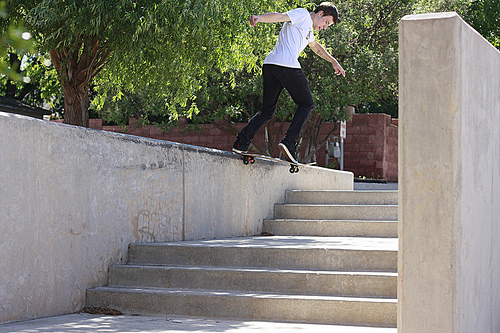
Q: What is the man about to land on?
A: Stairs.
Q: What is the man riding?
A: A skateboard.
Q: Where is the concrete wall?
A: Behind the skateboarder.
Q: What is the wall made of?
A: Concrete.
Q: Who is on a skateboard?
A: A young man.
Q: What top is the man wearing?
A: A white tee shirt.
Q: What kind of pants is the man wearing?
A: Black denim.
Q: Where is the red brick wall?
A: To the skateboarder's left.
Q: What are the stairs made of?
A: Concrete.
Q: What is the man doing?
A: A skateboard trick.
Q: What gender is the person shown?
A: Male.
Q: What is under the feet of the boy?
A: Skateboard.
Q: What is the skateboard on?
A: Edge of a wall.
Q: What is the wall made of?
A: Concrete.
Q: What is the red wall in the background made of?
A: Brick.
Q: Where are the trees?
A: Behind the boy.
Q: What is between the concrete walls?
A: Steps.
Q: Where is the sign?
A: In front of the brick wall.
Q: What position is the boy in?
A: Standing.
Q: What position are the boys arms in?
A: Out to his sides.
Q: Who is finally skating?
A: The man.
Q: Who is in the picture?
A: A boy.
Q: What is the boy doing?
A: Skateboarding.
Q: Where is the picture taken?
A: Some stairs.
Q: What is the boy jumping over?
A: Stairs.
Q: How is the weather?
A: Sunny.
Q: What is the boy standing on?
A: A skateboard.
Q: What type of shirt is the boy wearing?
A: A white tee shirt.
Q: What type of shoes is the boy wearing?
A: Black keds.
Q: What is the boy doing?
A: Skateboarding.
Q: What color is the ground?
A: Gray.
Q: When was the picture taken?
A: Daytime.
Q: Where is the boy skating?
A: On steps.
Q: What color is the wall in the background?
A: Brown.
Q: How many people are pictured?
A: 1.